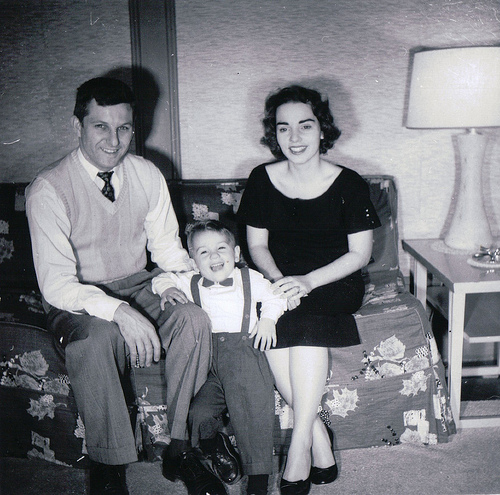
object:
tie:
[97, 171, 116, 202]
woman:
[234, 84, 383, 495]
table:
[399, 237, 500, 428]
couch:
[0, 173, 459, 468]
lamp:
[406, 45, 500, 252]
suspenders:
[151, 268, 287, 335]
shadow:
[105, 65, 188, 271]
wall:
[0, 0, 500, 307]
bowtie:
[202, 276, 234, 288]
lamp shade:
[405, 45, 499, 131]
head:
[260, 85, 342, 166]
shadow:
[246, 75, 363, 160]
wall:
[202, 108, 254, 154]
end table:
[399, 238, 500, 429]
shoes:
[84, 445, 231, 495]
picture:
[0, 0, 497, 495]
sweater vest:
[25, 145, 162, 314]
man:
[24, 76, 231, 495]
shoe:
[278, 478, 309, 495]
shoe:
[309, 423, 338, 484]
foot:
[281, 443, 311, 481]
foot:
[309, 422, 338, 485]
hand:
[270, 267, 315, 301]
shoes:
[279, 414, 338, 495]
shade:
[401, 45, 500, 130]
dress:
[239, 159, 382, 349]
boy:
[151, 220, 288, 495]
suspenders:
[190, 267, 251, 333]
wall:
[162, 0, 500, 393]